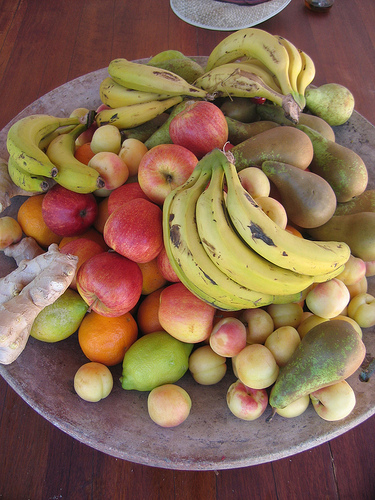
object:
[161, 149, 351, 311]
bananas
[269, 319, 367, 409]
pear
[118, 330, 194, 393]
lemon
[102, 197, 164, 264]
apple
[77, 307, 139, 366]
orange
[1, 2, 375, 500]
table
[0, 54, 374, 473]
tray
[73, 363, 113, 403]
peach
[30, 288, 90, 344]
lime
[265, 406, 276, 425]
stem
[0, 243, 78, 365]
ginger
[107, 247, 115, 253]
stem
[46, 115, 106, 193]
banana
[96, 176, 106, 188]
end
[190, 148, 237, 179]
handle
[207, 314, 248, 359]
peaches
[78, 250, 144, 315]
apple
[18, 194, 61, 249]
fruit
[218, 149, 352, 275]
banana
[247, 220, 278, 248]
bruise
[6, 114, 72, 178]
banana